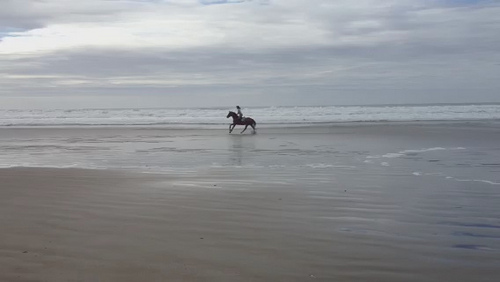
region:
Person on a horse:
[205, 90, 277, 149]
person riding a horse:
[211, 101, 266, 134]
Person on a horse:
[213, 106, 268, 133]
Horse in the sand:
[216, 104, 281, 155]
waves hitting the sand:
[121, 101, 199, 137]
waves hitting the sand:
[312, 102, 402, 149]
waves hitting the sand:
[75, 111, 140, 144]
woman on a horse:
[229, 102, 242, 123]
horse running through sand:
[223, 101, 258, 133]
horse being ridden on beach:
[218, 98, 269, 145]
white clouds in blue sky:
[15, 11, 72, 52]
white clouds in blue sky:
[55, 46, 117, 81]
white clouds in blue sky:
[8, 58, 63, 98]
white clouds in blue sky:
[88, 74, 152, 111]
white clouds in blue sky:
[102, 10, 206, 62]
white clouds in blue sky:
[222, 28, 294, 62]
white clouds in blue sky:
[328, 17, 413, 67]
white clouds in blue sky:
[271, 58, 341, 102]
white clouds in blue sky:
[366, 26, 458, 84]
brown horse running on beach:
[217, 102, 262, 148]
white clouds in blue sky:
[8, 5, 62, 40]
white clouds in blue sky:
[26, 36, 60, 76]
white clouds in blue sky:
[22, 80, 91, 121]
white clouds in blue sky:
[75, 11, 150, 70]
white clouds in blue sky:
[79, 39, 143, 92]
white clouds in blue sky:
[158, 17, 244, 63]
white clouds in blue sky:
[167, 44, 228, 78]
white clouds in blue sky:
[251, 17, 345, 70]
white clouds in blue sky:
[327, 52, 430, 112]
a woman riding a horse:
[220, 103, 262, 135]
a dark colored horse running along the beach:
[223, 110, 258, 135]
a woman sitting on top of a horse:
[233, 104, 245, 121]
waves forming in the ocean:
[0, 102, 497, 122]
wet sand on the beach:
[0, 171, 499, 278]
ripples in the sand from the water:
[315, 187, 499, 279]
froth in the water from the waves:
[361, 137, 467, 164]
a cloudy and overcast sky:
[0, 0, 499, 105]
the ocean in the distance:
[1, 102, 499, 124]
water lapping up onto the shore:
[1, 142, 197, 179]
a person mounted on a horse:
[233, 104, 244, 119]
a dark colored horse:
[225, 110, 258, 135]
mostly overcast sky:
[1, 0, 498, 114]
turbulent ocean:
[0, 100, 497, 126]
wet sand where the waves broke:
[0, 119, 495, 188]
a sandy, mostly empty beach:
[1, 118, 498, 280]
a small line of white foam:
[361, 143, 465, 165]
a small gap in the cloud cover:
[0, 21, 36, 45]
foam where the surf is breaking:
[0, 100, 497, 127]